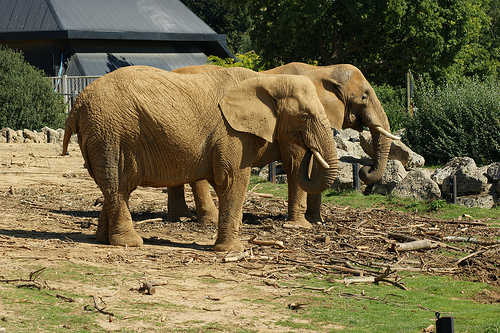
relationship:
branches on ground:
[324, 206, 487, 277] [2, 194, 499, 326]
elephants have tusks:
[71, 67, 394, 255] [311, 148, 330, 171]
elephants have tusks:
[71, 67, 394, 255] [378, 126, 402, 145]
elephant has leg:
[71, 67, 394, 255] [103, 181, 147, 251]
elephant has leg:
[71, 67, 394, 255] [220, 181, 245, 252]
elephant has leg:
[71, 67, 394, 255] [95, 199, 112, 241]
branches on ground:
[324, 217, 500, 276] [2, 194, 499, 326]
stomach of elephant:
[119, 129, 208, 183] [71, 67, 394, 255]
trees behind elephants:
[232, 0, 499, 62] [71, 67, 394, 255]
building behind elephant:
[5, 1, 220, 76] [325, 62, 394, 190]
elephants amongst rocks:
[71, 67, 394, 255] [389, 146, 497, 207]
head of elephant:
[224, 70, 347, 201] [71, 67, 394, 255]